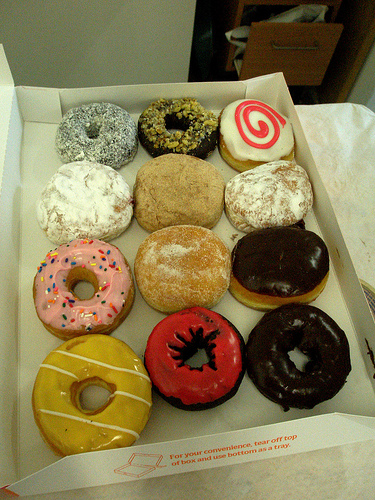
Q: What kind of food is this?
A: Donuts.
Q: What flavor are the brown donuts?
A: Chocolate.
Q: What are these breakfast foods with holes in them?
A: Donuts.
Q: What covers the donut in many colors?
A: Icing.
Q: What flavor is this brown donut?
A: Chocolate.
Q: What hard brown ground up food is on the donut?
A: Nuts.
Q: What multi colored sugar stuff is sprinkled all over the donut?
A: Sprinkles.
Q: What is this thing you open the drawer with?
A: Handle.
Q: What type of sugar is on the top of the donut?
A: Powdered sugar.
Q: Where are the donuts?
A: The box.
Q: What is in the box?
A: Donuts.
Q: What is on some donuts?
A: Frosting.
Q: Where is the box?
A: The table.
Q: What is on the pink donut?
A: Sprinkles.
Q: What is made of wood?
A: Drawer.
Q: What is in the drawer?
A: Paper.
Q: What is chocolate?
A: Frosting on two donuts.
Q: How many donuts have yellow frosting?
A: One.